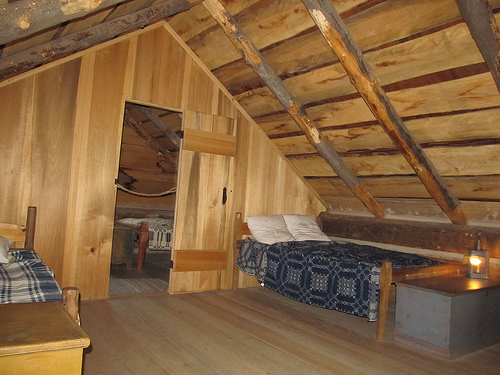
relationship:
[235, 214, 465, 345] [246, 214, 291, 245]
bed has pillow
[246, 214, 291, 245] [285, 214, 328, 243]
pillow by pillow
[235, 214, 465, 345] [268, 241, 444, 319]
bed has blanket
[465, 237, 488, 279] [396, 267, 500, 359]
light on table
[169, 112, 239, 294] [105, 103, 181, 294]
door leads to bedroom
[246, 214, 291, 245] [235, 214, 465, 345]
pillow on bed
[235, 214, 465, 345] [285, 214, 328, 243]
bed has pillow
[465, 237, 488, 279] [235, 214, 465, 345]
light by bed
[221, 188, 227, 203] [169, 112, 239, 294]
handle on door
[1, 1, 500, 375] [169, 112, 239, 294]
cabin has door